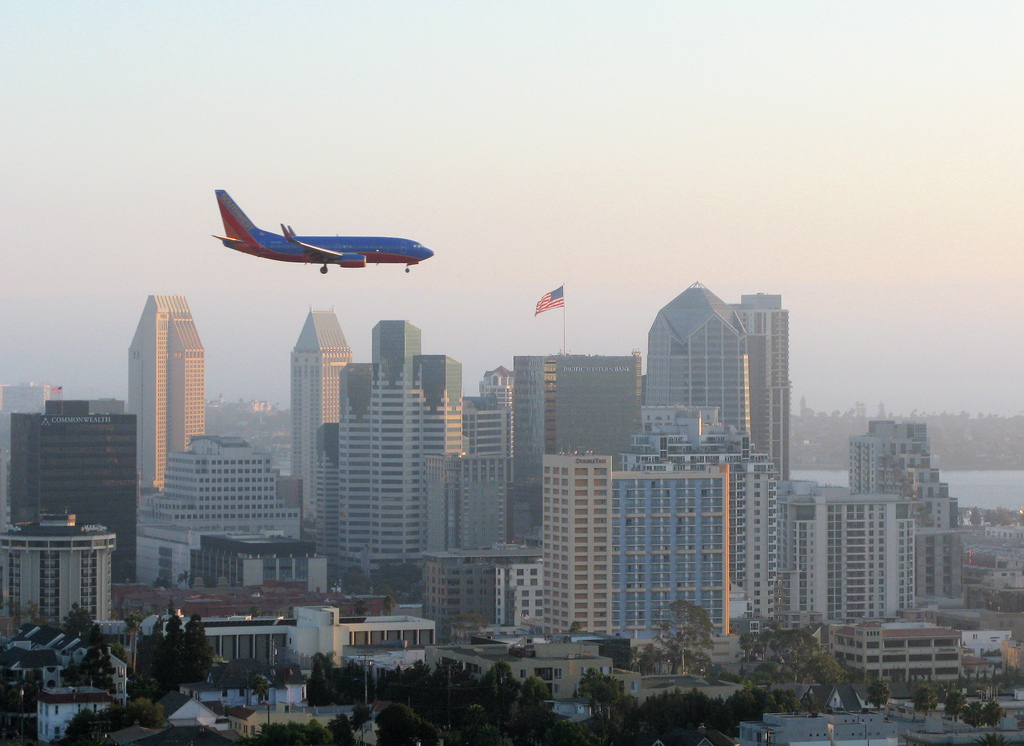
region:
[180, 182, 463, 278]
blue plane in air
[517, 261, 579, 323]
flag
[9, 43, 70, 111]
white clouds in blue sky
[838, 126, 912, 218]
white clouds in blue sky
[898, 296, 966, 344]
white clouds in blue sky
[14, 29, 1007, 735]
airplane flying low over a city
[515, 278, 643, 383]
flag flying on top of a pole on top of a roof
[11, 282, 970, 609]
geometric shapes of buildings and skyscrapers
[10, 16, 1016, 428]
hazy pink and blue sky over city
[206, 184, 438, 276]
horizontal blue plane with red highlights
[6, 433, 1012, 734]
trees and shorter buildings in front of skysvcrapers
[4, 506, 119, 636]
curved building with upper rim and stripes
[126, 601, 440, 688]
wide building with centered tower and line of windows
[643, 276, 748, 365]
zigzag design on top of pointed building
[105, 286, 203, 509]
a building in a city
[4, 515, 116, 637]
a building in a city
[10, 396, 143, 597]
a building in a city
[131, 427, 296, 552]
a building in a city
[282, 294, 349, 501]
a building in a city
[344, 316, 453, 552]
a building in a city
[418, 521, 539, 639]
a building in a city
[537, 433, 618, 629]
a building in a city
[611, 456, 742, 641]
a building in a city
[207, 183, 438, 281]
Blue and red plane in the sky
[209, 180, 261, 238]
Tail on an airplane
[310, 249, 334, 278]
Landing gear on an airplane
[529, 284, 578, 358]
American flag on top of a building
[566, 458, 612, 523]
Windows on a building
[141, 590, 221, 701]
Tall green trees in a city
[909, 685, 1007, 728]
Round green trees in a city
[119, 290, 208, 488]
A tall building in a city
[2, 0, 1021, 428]
Sky behind a city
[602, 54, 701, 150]
white clouds in the blue sky